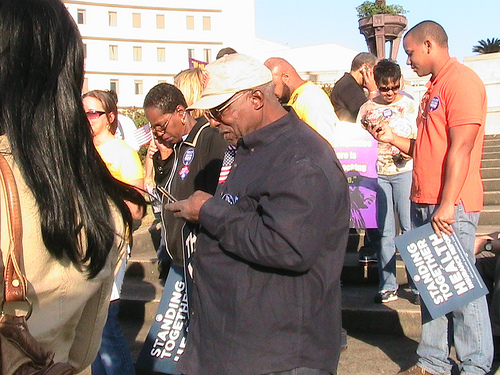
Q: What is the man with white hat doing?
A: Using his phone.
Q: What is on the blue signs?
A: White letters.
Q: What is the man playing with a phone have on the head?
A: A White head.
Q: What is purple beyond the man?
A: A poster.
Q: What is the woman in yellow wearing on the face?
A: Purple sunglasses.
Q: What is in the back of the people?
A: A statue.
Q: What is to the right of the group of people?
A: A building.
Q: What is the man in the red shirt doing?
A: Looking at a phone.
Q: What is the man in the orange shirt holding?
A: A blue sign.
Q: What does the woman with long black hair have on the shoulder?
A: A strap.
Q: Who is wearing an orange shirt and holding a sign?
A: A man.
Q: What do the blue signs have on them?
A: White words.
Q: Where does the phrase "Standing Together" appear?
A: On the blue folder in the man's hand.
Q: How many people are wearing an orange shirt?
A: 1.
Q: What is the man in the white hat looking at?
A: Phone.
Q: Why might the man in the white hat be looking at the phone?
A: Check message.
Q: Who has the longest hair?
A: Person on left.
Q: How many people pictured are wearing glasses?
A: 4.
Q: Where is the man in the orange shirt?
A: On right.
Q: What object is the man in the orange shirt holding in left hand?
A: Sign.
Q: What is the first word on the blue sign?
A: Standing.